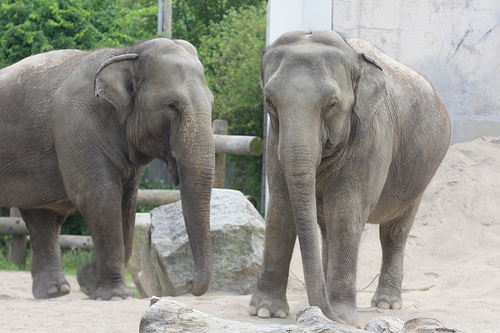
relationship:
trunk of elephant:
[172, 124, 217, 296] [0, 37, 216, 298]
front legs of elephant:
[75, 181, 139, 303] [0, 37, 216, 298]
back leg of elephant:
[16, 203, 71, 299] [0, 37, 216, 298]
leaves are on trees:
[13, 27, 51, 49] [1, 1, 264, 138]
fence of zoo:
[0, 131, 263, 260] [0, 1, 499, 333]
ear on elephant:
[93, 52, 141, 126] [0, 37, 216, 298]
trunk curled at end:
[172, 124, 217, 296] [181, 275, 212, 298]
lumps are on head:
[130, 39, 200, 61] [127, 37, 216, 185]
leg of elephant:
[247, 180, 290, 319] [246, 27, 453, 328]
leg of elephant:
[75, 181, 139, 303] [0, 37, 216, 298]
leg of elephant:
[16, 203, 71, 299] [0, 37, 216, 298]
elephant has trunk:
[0, 37, 216, 298] [172, 124, 217, 296]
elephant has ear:
[0, 37, 216, 298] [93, 52, 141, 126]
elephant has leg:
[0, 37, 216, 298] [16, 203, 71, 299]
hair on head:
[156, 32, 171, 40] [127, 37, 216, 185]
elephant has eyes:
[0, 37, 216, 298] [161, 100, 180, 114]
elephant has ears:
[0, 37, 216, 298] [93, 52, 141, 126]